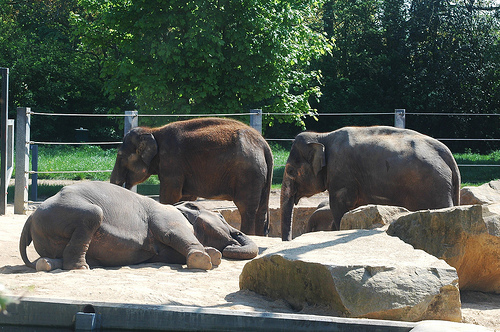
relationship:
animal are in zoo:
[276, 125, 463, 240] [18, 14, 489, 318]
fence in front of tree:
[14, 108, 500, 214] [333, 0, 484, 122]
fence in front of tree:
[14, 108, 500, 214] [75, 2, 326, 124]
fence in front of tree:
[14, 108, 500, 214] [0, 0, 118, 140]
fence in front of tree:
[14, 108, 500, 214] [398, 1, 494, 154]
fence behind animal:
[14, 108, 500, 214] [276, 125, 463, 240]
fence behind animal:
[14, 108, 500, 214] [112, 116, 273, 237]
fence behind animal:
[14, 108, 500, 214] [18, 178, 259, 271]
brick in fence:
[6, 95, 40, 225] [5, 99, 36, 210]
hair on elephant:
[190, 115, 223, 142] [120, 112, 317, 194]